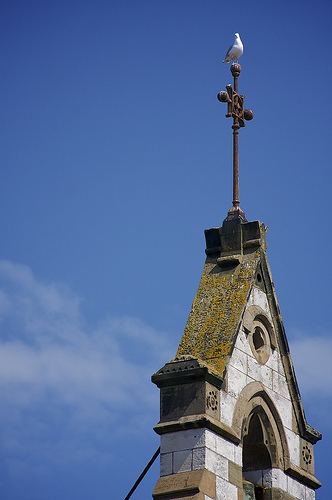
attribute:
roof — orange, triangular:
[151, 221, 324, 438]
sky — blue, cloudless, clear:
[2, 2, 330, 500]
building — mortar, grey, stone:
[125, 62, 323, 495]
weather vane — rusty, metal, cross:
[217, 62, 252, 212]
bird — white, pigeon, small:
[222, 31, 243, 63]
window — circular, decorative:
[251, 329, 264, 350]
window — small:
[239, 413, 272, 499]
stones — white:
[239, 358, 274, 388]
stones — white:
[156, 428, 215, 451]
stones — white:
[189, 449, 218, 466]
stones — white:
[261, 390, 293, 413]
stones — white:
[261, 468, 286, 491]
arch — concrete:
[233, 391, 291, 499]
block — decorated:
[158, 381, 222, 420]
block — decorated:
[297, 438, 316, 476]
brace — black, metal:
[125, 445, 160, 500]